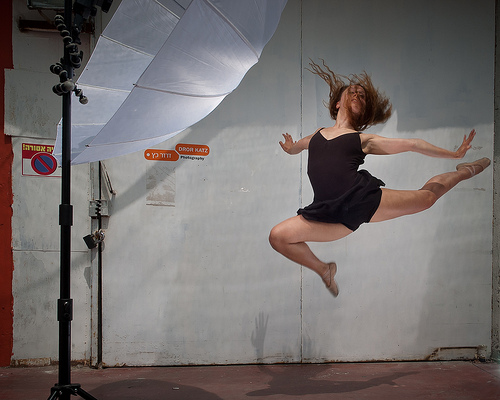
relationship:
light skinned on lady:
[267, 85, 481, 291] [265, 67, 497, 298]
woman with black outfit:
[259, 61, 492, 301] [297, 127, 386, 232]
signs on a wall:
[114, 127, 249, 241] [131, 113, 343, 310]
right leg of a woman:
[266, 207, 358, 298] [259, 61, 492, 301]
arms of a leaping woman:
[275, 123, 478, 163] [259, 61, 492, 301]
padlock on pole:
[79, 227, 106, 252] [95, 197, 105, 361]